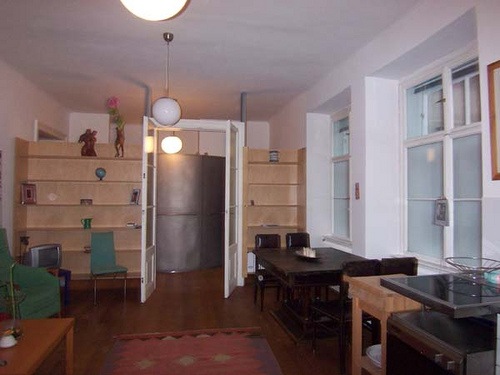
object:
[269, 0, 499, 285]
wall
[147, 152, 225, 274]
silver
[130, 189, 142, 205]
picture frame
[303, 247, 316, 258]
candles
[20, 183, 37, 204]
picture frame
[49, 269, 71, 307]
table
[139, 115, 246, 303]
doors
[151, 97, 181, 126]
light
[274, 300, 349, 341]
dark rug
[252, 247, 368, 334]
diningroom table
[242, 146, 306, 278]
shelf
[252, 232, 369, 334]
table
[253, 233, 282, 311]
chair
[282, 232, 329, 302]
chair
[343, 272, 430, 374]
chair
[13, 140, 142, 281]
bookcase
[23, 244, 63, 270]
television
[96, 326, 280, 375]
rug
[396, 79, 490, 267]
door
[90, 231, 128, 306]
chair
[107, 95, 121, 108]
flower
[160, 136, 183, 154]
globe light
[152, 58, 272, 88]
ceiling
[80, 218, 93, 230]
pitcher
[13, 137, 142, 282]
shelf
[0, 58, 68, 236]
wall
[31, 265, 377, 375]
floor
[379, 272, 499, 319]
counter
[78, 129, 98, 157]
sculpture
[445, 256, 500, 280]
basket